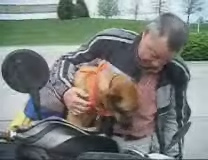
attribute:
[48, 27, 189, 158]
jacket — motorcycle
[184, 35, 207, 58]
bush — green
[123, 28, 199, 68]
man — sitting, looking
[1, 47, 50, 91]
mirror — round, black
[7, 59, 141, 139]
dog — brown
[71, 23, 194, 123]
jacket — black, gray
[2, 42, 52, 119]
mirror — black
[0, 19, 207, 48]
grass — short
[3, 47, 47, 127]
rearview mirror — black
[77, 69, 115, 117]
bandanna — red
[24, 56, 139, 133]
dog — brown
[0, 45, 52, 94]
mirror — rear, black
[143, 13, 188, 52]
hair — gray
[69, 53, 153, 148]
dog — brown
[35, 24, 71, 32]
grass — green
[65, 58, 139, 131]
brown dog — big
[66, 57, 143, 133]
dog — sitting, looking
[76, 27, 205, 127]
coat — gray and black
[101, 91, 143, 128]
nose — black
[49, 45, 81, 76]
elbow — bent